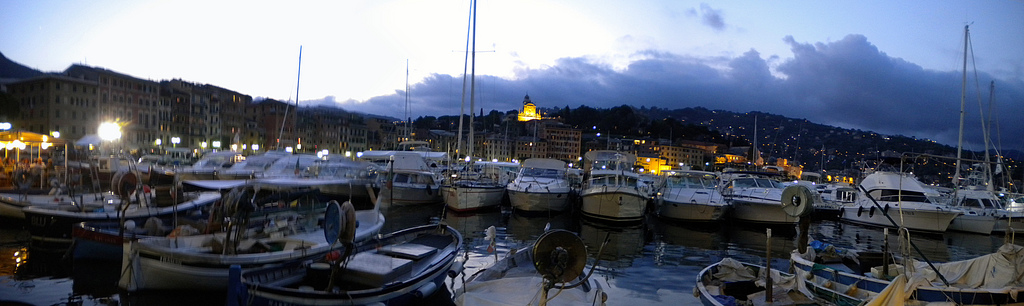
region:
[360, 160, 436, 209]
ship docked next to ship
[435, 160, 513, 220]
ship docked next to shipship docked next to ship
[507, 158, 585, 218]
ship docked next to ship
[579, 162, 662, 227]
ship docked next to ship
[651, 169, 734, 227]
ship docked next to ship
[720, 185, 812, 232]
ship docked next to ship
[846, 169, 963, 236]
ship docked next to ship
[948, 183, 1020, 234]
ship docked next to ship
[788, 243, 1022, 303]
ship docked next to ship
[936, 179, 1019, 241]
White boat in the water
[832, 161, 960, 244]
White boat in the water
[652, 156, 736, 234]
White boat in the water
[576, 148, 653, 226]
White boat in the water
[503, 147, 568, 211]
White boat in the water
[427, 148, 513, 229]
White boat in the water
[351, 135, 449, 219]
White boat in the water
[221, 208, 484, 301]
White boat in the water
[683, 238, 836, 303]
White boat in the water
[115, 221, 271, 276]
boat on the water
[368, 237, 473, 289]
boat on the water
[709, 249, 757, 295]
boat on the water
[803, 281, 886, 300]
boat on the water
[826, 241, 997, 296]
boat on the water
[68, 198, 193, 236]
boat on the water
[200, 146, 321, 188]
boat on the water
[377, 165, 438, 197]
boat on the water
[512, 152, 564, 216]
boat on the water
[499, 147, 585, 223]
the boat is white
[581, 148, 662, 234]
the boat is white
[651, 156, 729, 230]
the boat is white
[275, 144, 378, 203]
the boat is white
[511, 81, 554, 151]
a light above a boat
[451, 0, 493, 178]
the mast of a boat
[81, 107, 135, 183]
light on a boat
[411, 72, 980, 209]
trees on a coline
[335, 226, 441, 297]
the sit of a boat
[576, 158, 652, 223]
boat docked in water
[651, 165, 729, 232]
boat docked in water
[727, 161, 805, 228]
boat docked in water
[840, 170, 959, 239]
boat docked in water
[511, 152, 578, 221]
boat docked in water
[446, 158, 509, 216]
boat docked in water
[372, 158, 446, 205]
boat docked in water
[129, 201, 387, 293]
boat docked in water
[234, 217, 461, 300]
boat docked in water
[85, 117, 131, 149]
large light among rows of boats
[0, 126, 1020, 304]
whole bunch of boats sitting in water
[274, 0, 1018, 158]
dark clouds hanging in sky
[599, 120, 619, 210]
a boat in the water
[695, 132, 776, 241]
a boat in the water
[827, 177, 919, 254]
a boat in the water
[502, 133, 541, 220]
a boat in the water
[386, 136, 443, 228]
a boat in the water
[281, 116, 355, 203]
a boat in the water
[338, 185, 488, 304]
a boat in the water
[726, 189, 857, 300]
a boat in the water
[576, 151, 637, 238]
boat docked in pier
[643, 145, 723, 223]
boat docked in pier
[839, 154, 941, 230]
boat docked in pier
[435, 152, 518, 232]
boat docked in pier